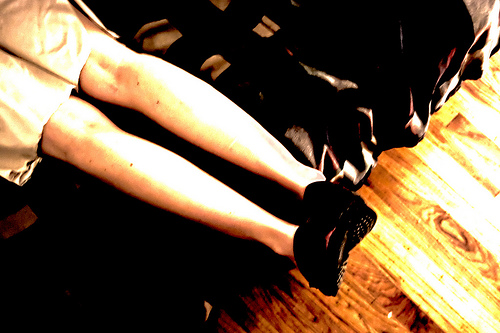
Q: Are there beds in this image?
A: Yes, there is a bed.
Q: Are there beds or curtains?
A: Yes, there is a bed.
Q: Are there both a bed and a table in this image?
A: No, there is a bed but no tables.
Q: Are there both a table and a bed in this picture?
A: No, there is a bed but no tables.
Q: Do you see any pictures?
A: No, there are no pictures.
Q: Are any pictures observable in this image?
A: No, there are no pictures.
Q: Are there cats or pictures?
A: No, there are no pictures or cats.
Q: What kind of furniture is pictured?
A: The furniture is a bed.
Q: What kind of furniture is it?
A: The piece of furniture is a bed.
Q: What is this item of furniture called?
A: This is a bed.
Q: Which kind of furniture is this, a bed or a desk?
A: This is a bed.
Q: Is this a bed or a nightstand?
A: This is a bed.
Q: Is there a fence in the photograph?
A: No, there are no fences.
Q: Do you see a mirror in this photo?
A: No, there are no mirrors.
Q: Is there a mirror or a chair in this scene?
A: No, there are no mirrors or chairs.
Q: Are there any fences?
A: No, there are no fences.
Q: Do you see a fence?
A: No, there are no fences.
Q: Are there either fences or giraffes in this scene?
A: No, there are no fences or giraffes.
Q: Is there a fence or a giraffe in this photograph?
A: No, there are no fences or giraffes.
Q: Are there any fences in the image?
A: No, there are no fences.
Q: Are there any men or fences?
A: No, there are no fences or men.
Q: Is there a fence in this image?
A: No, there are no fences.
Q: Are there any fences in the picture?
A: No, there are no fences.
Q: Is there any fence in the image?
A: No, there are no fences.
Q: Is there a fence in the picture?
A: No, there are no fences.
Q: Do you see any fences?
A: No, there are no fences.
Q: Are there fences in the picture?
A: No, there are no fences.